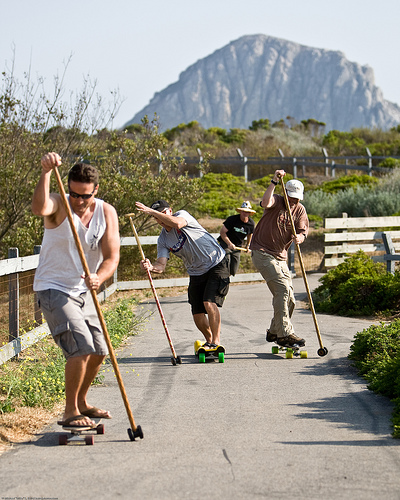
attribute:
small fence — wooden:
[0, 235, 271, 367]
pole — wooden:
[123, 211, 181, 366]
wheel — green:
[194, 352, 205, 365]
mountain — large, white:
[118, 30, 387, 134]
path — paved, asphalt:
[2, 269, 387, 493]